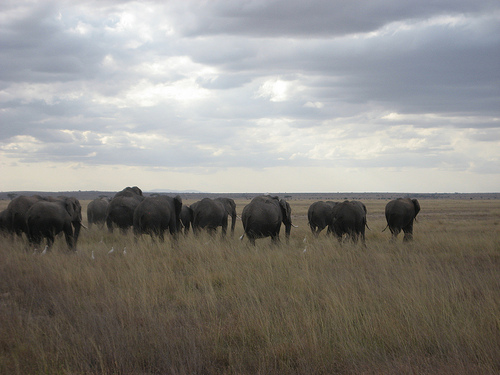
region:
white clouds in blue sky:
[125, 62, 210, 129]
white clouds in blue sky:
[297, 82, 364, 123]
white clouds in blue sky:
[368, 78, 472, 126]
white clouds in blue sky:
[97, 71, 147, 116]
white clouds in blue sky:
[147, 46, 197, 81]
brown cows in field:
[17, 196, 442, 254]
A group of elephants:
[13, 124, 432, 281]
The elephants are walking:
[33, 149, 436, 273]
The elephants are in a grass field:
[9, 148, 486, 367]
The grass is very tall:
[12, 236, 489, 368]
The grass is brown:
[6, 235, 482, 368]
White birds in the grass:
[26, 229, 151, 271]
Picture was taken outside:
[20, 14, 483, 339]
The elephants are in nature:
[10, 23, 477, 358]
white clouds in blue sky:
[15, 44, 77, 80]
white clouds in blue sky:
[356, 62, 391, 111]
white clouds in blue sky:
[365, 12, 447, 69]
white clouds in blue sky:
[223, 55, 315, 93]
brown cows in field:
[15, 175, 440, 267]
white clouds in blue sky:
[330, 55, 349, 80]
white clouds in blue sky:
[187, 51, 266, 141]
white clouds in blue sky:
[82, 104, 124, 134]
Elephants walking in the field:
[28, 159, 424, 242]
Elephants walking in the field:
[298, 165, 433, 256]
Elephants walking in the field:
[187, 184, 299, 244]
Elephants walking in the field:
[89, 185, 196, 238]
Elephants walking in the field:
[8, 184, 91, 254]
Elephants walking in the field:
[81, 174, 238, 244]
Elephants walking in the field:
[235, 179, 432, 249]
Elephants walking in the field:
[78, 164, 431, 251]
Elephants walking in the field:
[5, 170, 427, 256]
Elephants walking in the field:
[83, 175, 427, 251]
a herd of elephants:
[0, 184, 421, 256]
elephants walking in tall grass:
[1, 186, 422, 273]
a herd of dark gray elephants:
[0, 184, 422, 256]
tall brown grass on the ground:
[2, 259, 498, 374]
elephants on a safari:
[2, 183, 424, 328]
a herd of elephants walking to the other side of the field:
[0, 185, 496, 371]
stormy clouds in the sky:
[0, 2, 496, 118]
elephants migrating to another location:
[0, 185, 421, 260]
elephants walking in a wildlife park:
[2, 180, 422, 320]